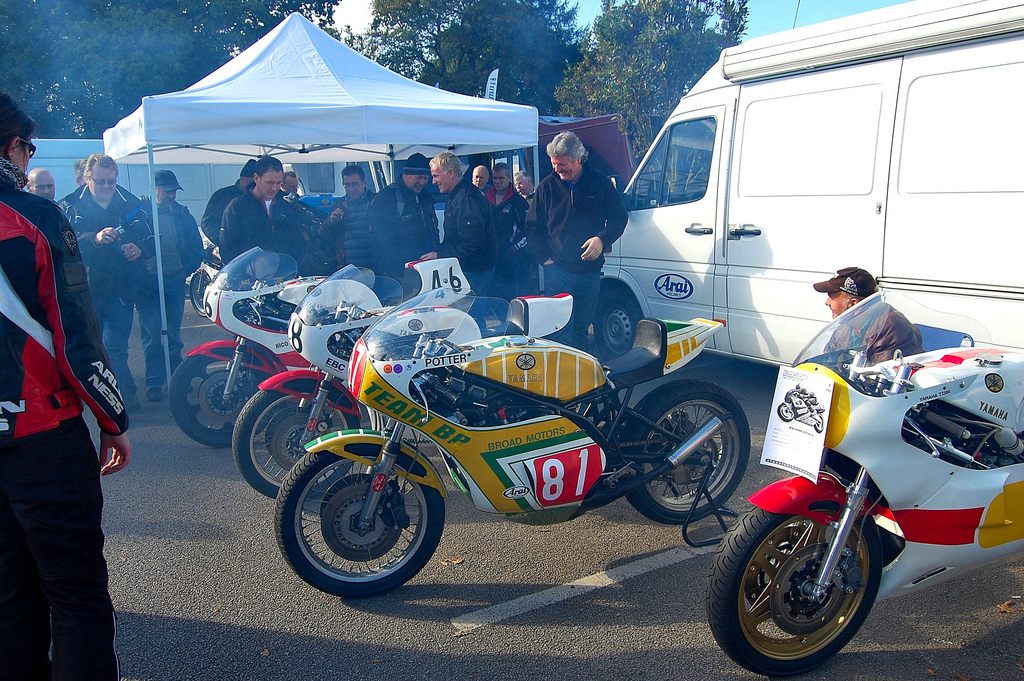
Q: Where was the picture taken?
A: At a motorcycle show.